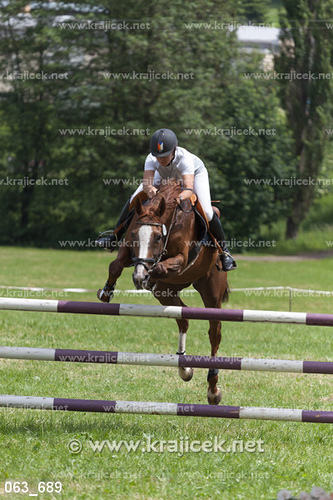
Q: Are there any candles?
A: No, there are no candles.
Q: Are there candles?
A: No, there are no candles.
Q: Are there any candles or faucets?
A: No, there are no candles or faucets.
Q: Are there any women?
A: Yes, there is a woman.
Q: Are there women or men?
A: Yes, there is a woman.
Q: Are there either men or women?
A: Yes, there is a woman.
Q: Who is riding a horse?
A: The woman is riding a horse.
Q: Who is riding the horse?
A: The woman is riding a horse.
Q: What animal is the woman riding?
A: The woman is riding a horse.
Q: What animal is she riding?
A: The woman is riding a horse.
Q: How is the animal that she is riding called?
A: The animal is a horse.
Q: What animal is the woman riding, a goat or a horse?
A: The woman is riding a horse.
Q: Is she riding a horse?
A: Yes, the woman is riding a horse.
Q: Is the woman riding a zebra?
A: No, the woman is riding a horse.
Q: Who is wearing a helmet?
A: The woman is wearing a helmet.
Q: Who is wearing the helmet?
A: The woman is wearing a helmet.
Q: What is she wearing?
A: The woman is wearing a helmet.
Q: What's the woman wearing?
A: The woman is wearing a helmet.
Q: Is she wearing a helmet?
A: Yes, the woman is wearing a helmet.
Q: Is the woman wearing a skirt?
A: No, the woman is wearing a helmet.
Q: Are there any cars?
A: No, there are no cars.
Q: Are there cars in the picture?
A: No, there are no cars.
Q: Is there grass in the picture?
A: Yes, there is grass.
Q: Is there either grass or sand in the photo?
A: Yes, there is grass.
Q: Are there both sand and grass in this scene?
A: No, there is grass but no sand.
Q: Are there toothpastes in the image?
A: No, there are no toothpastes.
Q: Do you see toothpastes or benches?
A: No, there are no toothpastes or benches.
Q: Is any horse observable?
A: Yes, there is a horse.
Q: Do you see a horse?
A: Yes, there is a horse.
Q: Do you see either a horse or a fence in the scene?
A: Yes, there is a horse.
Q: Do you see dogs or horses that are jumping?
A: Yes, the horse is jumping.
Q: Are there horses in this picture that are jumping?
A: Yes, there is a horse that is jumping.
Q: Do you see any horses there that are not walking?
A: Yes, there is a horse that is jumping .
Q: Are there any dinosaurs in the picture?
A: No, there are no dinosaurs.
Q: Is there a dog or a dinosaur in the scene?
A: No, there are no dinosaurs or dogs.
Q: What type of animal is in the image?
A: The animal is a horse.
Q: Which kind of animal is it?
A: The animal is a horse.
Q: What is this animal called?
A: That is a horse.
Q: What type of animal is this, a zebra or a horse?
A: That is a horse.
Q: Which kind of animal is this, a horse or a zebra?
A: That is a horse.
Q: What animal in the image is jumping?
A: The animal is a horse.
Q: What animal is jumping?
A: The animal is a horse.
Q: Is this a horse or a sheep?
A: This is a horse.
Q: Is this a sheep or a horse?
A: This is a horse.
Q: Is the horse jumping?
A: Yes, the horse is jumping.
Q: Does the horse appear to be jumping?
A: Yes, the horse is jumping.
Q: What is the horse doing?
A: The horse is jumping.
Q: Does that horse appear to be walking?
A: No, the horse is jumping.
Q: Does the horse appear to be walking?
A: No, the horse is jumping.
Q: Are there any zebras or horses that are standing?
A: No, there is a horse but it is jumping.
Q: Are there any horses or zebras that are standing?
A: No, there is a horse but it is jumping.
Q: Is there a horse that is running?
A: No, there is a horse but it is jumping.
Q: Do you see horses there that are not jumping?
A: No, there is a horse but it is jumping.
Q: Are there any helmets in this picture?
A: Yes, there is a helmet.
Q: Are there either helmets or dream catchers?
A: Yes, there is a helmet.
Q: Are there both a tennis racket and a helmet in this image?
A: No, there is a helmet but no rackets.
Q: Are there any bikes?
A: No, there are no bikes.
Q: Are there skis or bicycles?
A: No, there are no bicycles or skis.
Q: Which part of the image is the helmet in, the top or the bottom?
A: The helmet is in the top of the image.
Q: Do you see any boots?
A: Yes, there are boots.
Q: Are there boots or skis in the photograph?
A: Yes, there are boots.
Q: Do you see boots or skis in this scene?
A: Yes, there are boots.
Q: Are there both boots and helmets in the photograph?
A: Yes, there are both boots and a helmet.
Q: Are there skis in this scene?
A: No, there are no skis.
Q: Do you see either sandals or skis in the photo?
A: No, there are no skis or sandals.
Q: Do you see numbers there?
A: Yes, there are numbers.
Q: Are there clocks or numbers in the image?
A: Yes, there are numbers.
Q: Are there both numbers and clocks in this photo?
A: No, there are numbers but no clocks.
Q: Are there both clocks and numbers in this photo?
A: No, there are numbers but no clocks.